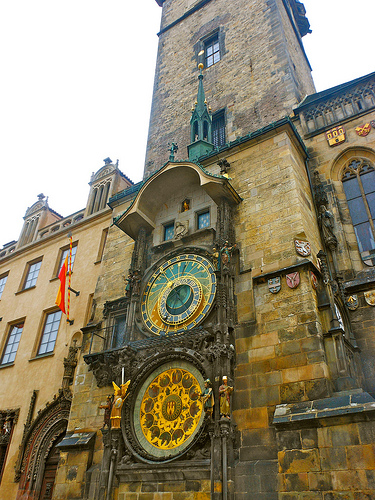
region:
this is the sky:
[37, 48, 97, 99]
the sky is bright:
[65, 38, 115, 93]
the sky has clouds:
[49, 72, 98, 123]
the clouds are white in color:
[53, 80, 102, 130]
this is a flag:
[55, 256, 70, 320]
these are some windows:
[2, 320, 58, 366]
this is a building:
[136, 42, 294, 498]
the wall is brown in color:
[84, 262, 90, 277]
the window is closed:
[26, 268, 36, 279]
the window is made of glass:
[42, 333, 55, 344]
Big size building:
[0, 4, 374, 499]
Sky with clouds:
[60, 30, 126, 117]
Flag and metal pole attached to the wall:
[51, 230, 86, 331]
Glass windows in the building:
[0, 266, 61, 368]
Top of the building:
[14, 146, 124, 211]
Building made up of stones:
[246, 332, 345, 478]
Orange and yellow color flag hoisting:
[50, 233, 78, 317]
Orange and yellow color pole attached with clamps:
[64, 283, 78, 326]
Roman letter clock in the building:
[133, 240, 222, 340]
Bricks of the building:
[233, 21, 283, 77]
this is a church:
[89, 67, 318, 497]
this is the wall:
[252, 308, 307, 362]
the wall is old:
[244, 315, 310, 385]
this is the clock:
[138, 249, 217, 330]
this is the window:
[34, 308, 58, 353]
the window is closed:
[37, 314, 58, 347]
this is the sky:
[49, 48, 140, 113]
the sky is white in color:
[32, 22, 142, 116]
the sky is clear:
[31, 8, 141, 105]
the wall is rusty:
[262, 310, 312, 370]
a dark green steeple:
[186, 61, 217, 155]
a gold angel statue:
[106, 378, 136, 429]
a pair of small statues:
[193, 374, 242, 424]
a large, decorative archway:
[15, 382, 80, 496]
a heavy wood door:
[39, 448, 59, 499]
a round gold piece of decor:
[130, 360, 209, 455]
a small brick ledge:
[112, 461, 219, 483]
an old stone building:
[58, 0, 366, 491]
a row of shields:
[262, 268, 320, 293]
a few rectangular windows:
[0, 241, 80, 360]